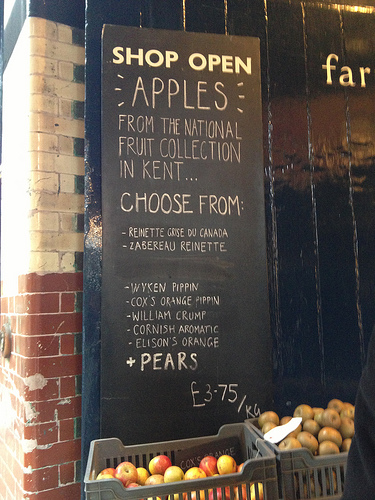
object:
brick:
[12, 291, 59, 316]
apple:
[149, 454, 172, 478]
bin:
[82, 423, 280, 499]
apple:
[199, 454, 219, 472]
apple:
[215, 454, 239, 476]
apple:
[114, 459, 139, 486]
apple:
[165, 465, 185, 487]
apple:
[182, 466, 209, 487]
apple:
[142, 473, 166, 492]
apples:
[115, 76, 245, 114]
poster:
[97, 22, 274, 442]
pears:
[138, 351, 200, 375]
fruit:
[116, 133, 157, 160]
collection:
[158, 140, 247, 165]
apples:
[95, 466, 116, 480]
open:
[186, 51, 255, 77]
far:
[320, 49, 374, 94]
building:
[1, 1, 374, 500]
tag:
[259, 414, 305, 446]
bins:
[250, 411, 368, 500]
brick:
[9, 290, 64, 319]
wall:
[0, 0, 90, 499]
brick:
[12, 312, 89, 339]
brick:
[9, 331, 65, 361]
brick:
[7, 374, 64, 406]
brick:
[26, 465, 69, 487]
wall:
[83, 0, 374, 499]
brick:
[15, 16, 62, 45]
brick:
[36, 38, 83, 57]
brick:
[16, 54, 62, 81]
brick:
[13, 92, 64, 120]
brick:
[16, 130, 64, 155]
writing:
[109, 44, 265, 421]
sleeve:
[338, 322, 374, 499]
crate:
[244, 397, 373, 498]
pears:
[259, 411, 280, 425]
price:
[185, 375, 267, 426]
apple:
[134, 465, 150, 487]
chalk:
[110, 72, 265, 422]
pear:
[319, 441, 337, 457]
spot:
[83, 213, 102, 255]